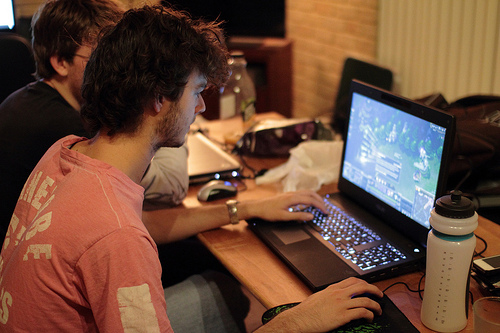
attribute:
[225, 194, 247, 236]
watch — silver 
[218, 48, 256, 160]
bottle — clear , plastic 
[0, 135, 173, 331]
shirt — red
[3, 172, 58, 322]
letters — white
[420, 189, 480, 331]
bottle — white 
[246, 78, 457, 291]
laptop — open 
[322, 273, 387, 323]
mousepad — black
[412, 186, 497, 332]
water bottle — white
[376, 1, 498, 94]
blinds — closed, white 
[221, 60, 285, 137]
bottle — empty , plastic 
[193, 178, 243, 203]
mouse — black , silver 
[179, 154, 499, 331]
table — brown, wooden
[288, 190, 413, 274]
keyboard — lit up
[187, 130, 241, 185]
laptop — closed 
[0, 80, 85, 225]
black shirt — black 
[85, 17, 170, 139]
hair — facial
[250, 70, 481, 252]
computer — silver, black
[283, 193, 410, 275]
computer keyboard — backlit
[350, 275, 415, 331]
mouse pad — black 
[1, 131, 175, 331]
t-shirt — pink 